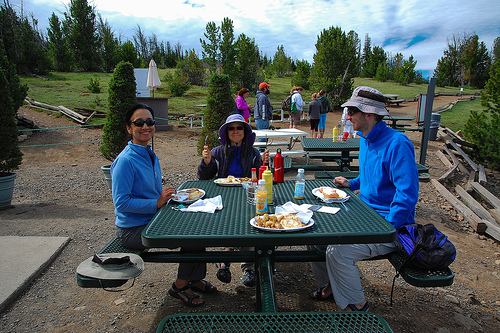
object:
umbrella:
[144, 57, 162, 97]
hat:
[340, 85, 392, 117]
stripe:
[356, 89, 390, 104]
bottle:
[259, 161, 268, 179]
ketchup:
[259, 169, 267, 180]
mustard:
[262, 171, 274, 204]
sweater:
[196, 145, 270, 181]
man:
[308, 85, 420, 313]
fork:
[201, 134, 210, 161]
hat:
[217, 113, 257, 146]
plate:
[250, 213, 316, 233]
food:
[280, 218, 303, 229]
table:
[136, 178, 396, 312]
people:
[106, 101, 219, 308]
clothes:
[346, 120, 421, 236]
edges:
[432, 104, 451, 114]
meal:
[316, 188, 343, 199]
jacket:
[108, 140, 165, 229]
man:
[252, 80, 274, 130]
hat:
[258, 81, 271, 91]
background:
[2, 0, 499, 155]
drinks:
[255, 191, 268, 215]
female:
[196, 114, 262, 288]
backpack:
[395, 222, 457, 271]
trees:
[192, 72, 239, 160]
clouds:
[442, 5, 488, 30]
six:
[234, 81, 332, 139]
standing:
[306, 91, 321, 140]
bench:
[149, 309, 395, 333]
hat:
[74, 250, 148, 293]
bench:
[72, 226, 144, 290]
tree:
[1, 48, 31, 177]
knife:
[262, 133, 270, 163]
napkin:
[180, 194, 224, 213]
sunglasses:
[226, 126, 245, 131]